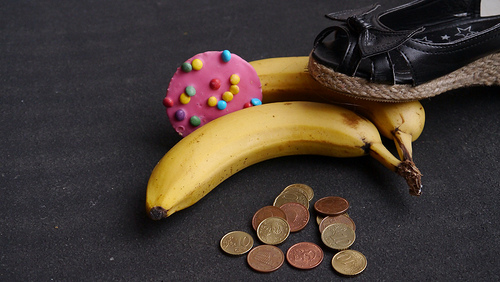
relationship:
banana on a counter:
[230, 52, 432, 167] [2, 4, 494, 279]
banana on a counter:
[139, 99, 394, 211] [2, 4, 494, 279]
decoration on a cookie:
[221, 48, 232, 64] [162, 46, 266, 138]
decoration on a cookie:
[249, 96, 261, 106] [162, 46, 266, 138]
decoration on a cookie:
[179, 61, 190, 71] [162, 46, 266, 138]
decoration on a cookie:
[186, 85, 196, 97] [162, 46, 266, 138]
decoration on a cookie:
[175, 109, 185, 121] [162, 46, 266, 138]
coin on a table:
[330, 245, 376, 280] [5, 5, 497, 265]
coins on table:
[222, 184, 368, 276] [26, 80, 93, 139]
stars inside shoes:
[412, 14, 484, 57] [302, 1, 488, 115]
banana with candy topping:
[144, 101, 423, 221] [189, 70, 224, 103]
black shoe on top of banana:
[301, 1, 499, 124] [200, 109, 375, 179]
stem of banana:
[366, 128, 424, 197] [167, 138, 257, 174]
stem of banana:
[366, 128, 424, 197] [115, 115, 420, 219]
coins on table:
[215, 173, 383, 280] [5, 5, 497, 265]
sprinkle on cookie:
[207, 72, 221, 92] [162, 46, 266, 138]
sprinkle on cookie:
[185, 79, 203, 106] [158, 41, 269, 143]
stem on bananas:
[353, 124, 426, 182] [124, 46, 456, 230]